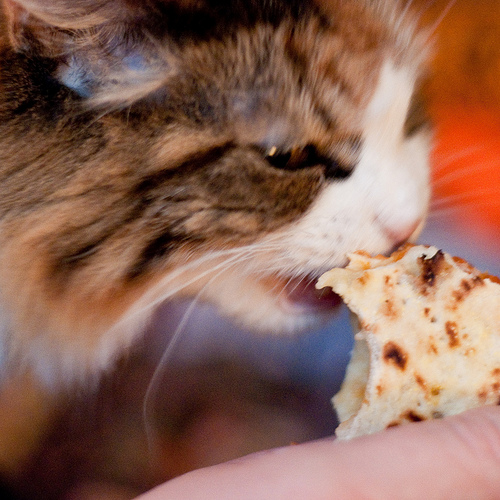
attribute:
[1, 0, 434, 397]
cat — hungry, brown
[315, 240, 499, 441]
food — tortilla, cheese crisp, brown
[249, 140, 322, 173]
eye — orange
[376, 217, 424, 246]
nose — pink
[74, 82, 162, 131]
hair — long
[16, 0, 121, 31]
hair — long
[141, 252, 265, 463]
whisker — white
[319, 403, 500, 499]
finger — large, pink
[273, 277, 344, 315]
lips — pink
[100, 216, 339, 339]
whisker — white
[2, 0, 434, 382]
fur — striped